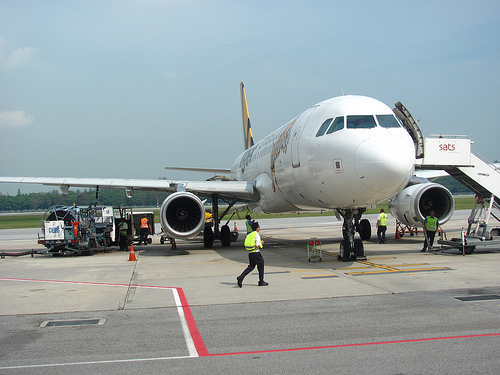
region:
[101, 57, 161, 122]
blue sky above the plane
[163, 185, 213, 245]
engine on the plane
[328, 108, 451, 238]
front of the plane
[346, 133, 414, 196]
nose of the plane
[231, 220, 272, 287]
worker next to train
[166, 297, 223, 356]
red and white line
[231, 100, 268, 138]
tail of the plane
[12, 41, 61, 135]
clouds in the sky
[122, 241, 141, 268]
orange and white cone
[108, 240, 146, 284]
cone on the ground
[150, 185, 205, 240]
a plane engine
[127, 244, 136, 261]
an orange and white cone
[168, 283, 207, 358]
a long red and white line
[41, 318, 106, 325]
a large drain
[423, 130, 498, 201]
part of a plane staircase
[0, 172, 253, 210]
the wing of a plane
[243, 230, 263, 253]
a green reflective vest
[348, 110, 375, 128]
the window of a plane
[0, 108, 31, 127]
a small white cloud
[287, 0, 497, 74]
part of a blue sky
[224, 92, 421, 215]
a white airplane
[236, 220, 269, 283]
a man wearing a neon green vest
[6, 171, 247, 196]
the right spoiler of an airplane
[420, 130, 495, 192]
stairs leading to the entrance of the airplane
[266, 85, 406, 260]
a white airplane on the ground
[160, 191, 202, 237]
an airplane's right jet engine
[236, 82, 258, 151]
an airplane's wing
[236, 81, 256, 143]
yellow and black airplane wing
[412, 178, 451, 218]
airplane's left jet engine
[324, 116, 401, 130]
cockpit of an airplane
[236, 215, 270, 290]
airport worker on the runeway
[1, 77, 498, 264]
airplane on the runeway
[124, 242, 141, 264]
orange cone on airport runway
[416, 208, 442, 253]
worker on airport runeway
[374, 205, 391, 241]
airport worker on the runway under an airplane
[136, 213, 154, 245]
airport worker wearing an orange safety vest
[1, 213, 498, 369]
airport runway with airplane on it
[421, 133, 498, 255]
portable passenger loading steps attached to airplane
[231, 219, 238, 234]
orange safety cone under airplane on the runway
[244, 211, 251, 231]
airport employee under a landed airplane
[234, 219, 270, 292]
man with yellow vest or bag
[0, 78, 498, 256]
big white airplane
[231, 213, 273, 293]
uniformed airport employee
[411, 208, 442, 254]
uniformed airport employee on tarmac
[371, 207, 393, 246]
airport employee showing us his back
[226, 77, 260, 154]
yellow and blue colored fin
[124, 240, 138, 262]
orange traffic cone with white stripe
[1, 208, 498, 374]
gray tarmac with red and white lines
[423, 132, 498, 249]
stairs used to exit an airplane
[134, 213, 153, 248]
airport employee wearing orange vest